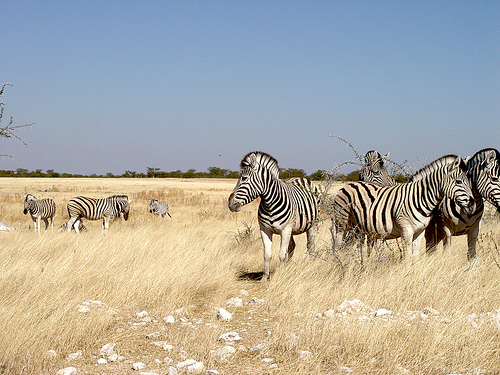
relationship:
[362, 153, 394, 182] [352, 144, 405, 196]
zebra in middle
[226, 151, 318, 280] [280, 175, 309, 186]
zebra has a back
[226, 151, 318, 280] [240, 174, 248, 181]
zebra has an eye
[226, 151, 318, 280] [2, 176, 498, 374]
zebra in grass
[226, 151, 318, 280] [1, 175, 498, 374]
zebra are in a field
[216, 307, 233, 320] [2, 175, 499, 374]
rock on ground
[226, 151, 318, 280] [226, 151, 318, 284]
zebra in a zebra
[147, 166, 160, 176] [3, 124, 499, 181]
tree in background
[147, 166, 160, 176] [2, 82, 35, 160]
tree has branches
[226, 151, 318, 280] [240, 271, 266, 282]
zebra has a shadow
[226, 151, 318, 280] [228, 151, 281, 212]
zebra has a head